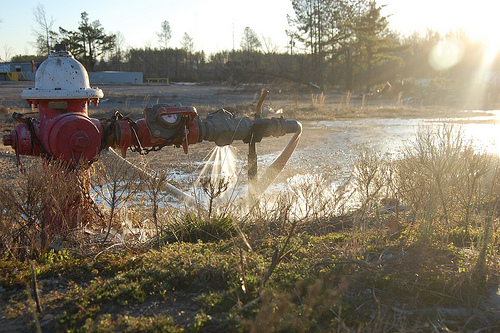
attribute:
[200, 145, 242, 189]
water — spraying